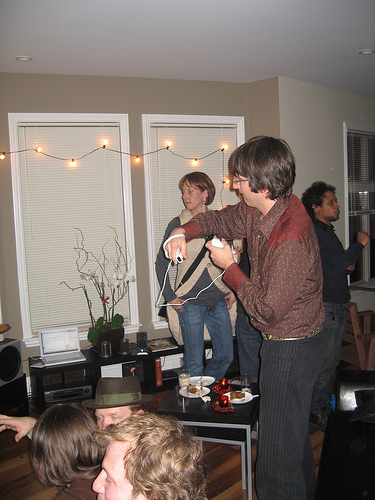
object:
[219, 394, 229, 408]
candles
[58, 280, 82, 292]
bow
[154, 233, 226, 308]
controller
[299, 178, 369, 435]
man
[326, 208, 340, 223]
goatee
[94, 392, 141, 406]
band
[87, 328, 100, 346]
leaves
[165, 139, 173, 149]
lights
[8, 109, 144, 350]
window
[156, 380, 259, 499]
table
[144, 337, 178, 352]
book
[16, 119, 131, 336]
blinds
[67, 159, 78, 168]
lights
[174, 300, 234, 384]
jeans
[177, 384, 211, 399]
plates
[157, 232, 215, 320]
purse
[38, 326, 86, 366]
laptop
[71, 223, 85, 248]
branches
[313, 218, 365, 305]
shirt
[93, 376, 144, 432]
head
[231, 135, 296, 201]
hair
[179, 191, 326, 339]
shirt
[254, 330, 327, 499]
pants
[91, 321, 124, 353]
pot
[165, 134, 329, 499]
man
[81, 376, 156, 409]
fedora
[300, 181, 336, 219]
hair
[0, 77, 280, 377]
walls